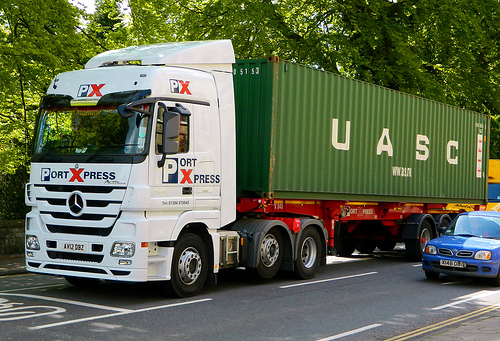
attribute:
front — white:
[27, 37, 237, 289]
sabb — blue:
[416, 205, 496, 284]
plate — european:
[38, 237, 83, 257]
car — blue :
[418, 210, 499, 292]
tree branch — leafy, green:
[252, 0, 349, 76]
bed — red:
[252, 186, 497, 224]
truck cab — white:
[17, 29, 249, 294]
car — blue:
[416, 201, 498, 290]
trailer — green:
[225, 18, 499, 275]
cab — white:
[24, 34, 250, 288]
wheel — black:
[158, 200, 215, 311]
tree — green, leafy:
[7, 5, 498, 64]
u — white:
[329, 115, 354, 152]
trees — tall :
[0, 0, 499, 256]